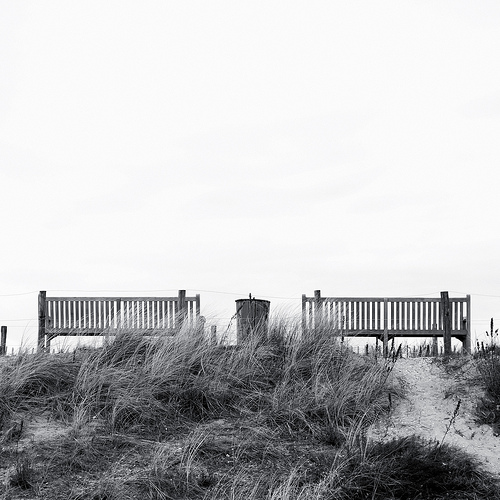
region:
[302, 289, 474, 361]
a park bench on the seashore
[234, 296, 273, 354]
a trash can on the seashore park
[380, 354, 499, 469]
beach sand leading out to the beach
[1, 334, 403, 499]
tall grass in the sand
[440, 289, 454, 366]
wooden security posts at the entrance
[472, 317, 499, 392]
wild sticker bush on the beach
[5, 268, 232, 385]
this is a bench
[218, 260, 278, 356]
this is a trash can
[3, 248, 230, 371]
bench facing the weeds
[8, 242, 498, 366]
two benches next to each other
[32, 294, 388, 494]
weeds growing in front of benches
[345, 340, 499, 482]
a path next to weeds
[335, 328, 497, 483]
the path is sand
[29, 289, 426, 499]
the wind is blowing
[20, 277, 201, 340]
vertical lines on bench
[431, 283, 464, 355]
post in front of bench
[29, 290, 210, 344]
the bench to the left side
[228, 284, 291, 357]
The trash can in the midle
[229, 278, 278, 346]
The trash can is in the middle of the benches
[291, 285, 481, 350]
The bench to the right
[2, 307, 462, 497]
The grass is growing high behind the bench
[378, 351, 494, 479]
The dirt patch area near the grass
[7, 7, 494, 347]
The sky is clear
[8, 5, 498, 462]
The photo is in black and white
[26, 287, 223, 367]
The bench is made of wood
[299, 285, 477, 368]
The bench is facing the sky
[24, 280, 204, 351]
This is a fence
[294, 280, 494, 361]
This is a fence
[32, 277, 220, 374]
This is a fence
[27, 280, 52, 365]
This is a pole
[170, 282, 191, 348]
This is a pole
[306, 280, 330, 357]
This is a pole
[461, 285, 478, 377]
This is a pole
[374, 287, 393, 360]
This is a pole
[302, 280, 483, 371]
wooden fence on right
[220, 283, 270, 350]
trash can in middle of fences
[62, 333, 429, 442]
long billowing grass in front of fences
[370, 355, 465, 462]
dirt and sand pathway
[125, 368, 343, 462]
dry long grasses on hill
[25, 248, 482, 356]
two fences and a trash can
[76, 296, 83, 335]
a wood on a bench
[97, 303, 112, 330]
a wood on a bench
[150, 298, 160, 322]
a wood on a bench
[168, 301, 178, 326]
a wood on a bench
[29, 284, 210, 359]
A wooden bench.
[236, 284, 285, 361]
A trash can.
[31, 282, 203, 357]
bench on the left side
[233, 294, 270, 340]
trashcan beside the bench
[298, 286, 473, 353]
bench on the right side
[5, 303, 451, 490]
long grass in front of the benches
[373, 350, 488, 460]
dirt path beside the long grass